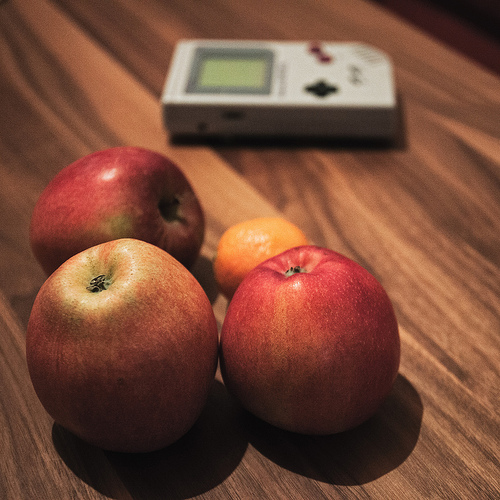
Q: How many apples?
A: Three.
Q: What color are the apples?
A: Red.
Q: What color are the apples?
A: Red.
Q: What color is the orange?
A: Orange.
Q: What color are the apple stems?
A: Brown.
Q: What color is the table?
A: Brown.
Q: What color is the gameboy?
A: Gray.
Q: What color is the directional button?
A: Black.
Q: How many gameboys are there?
A: One.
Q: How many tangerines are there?
A: One.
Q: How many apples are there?
A: 3.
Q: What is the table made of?
A: Wood.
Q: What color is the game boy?
A: Gray.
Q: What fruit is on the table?
A: Apples and tangerine.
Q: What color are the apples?
A: Red.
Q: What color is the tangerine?
A: Orange.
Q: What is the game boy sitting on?
A: A table.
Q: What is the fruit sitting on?
A: A table.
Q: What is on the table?
A: Fruit and a game boy.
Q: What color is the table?
A: Brown.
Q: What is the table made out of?
A: Wood.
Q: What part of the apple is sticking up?
A: The bottom.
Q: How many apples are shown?
A: 3.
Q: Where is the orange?
A: Behind the apples.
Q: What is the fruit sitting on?
A: Table.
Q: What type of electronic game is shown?
A: Gameboy.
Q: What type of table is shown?
A: Wooden.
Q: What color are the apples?
A: Red.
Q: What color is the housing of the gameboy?
A: Gray.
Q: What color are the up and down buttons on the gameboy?
A: Black.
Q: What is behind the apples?
A: Gameboy.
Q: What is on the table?
A: Apples.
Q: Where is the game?
A: Behind the apples.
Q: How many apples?
A: 3.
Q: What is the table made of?
A: Wood.